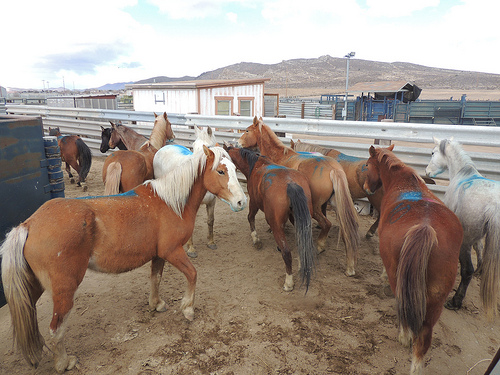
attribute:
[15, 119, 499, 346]
horses — gathered, walking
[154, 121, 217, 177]
horse — white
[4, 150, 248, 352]
horse — dirty, white, brown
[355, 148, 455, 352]
horse — brown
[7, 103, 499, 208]
fence — metal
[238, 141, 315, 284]
horse — brown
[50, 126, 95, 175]
horse — turning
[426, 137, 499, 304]
horse — white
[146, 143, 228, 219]
mane — white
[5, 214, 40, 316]
tail — white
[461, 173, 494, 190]
paint — blue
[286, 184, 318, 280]
tail — black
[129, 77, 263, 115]
building — small, white